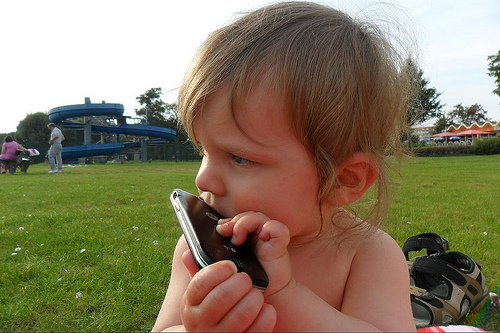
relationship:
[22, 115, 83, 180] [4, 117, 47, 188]
man and woman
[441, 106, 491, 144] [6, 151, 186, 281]
canopy at park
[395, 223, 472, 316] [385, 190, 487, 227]
item on ground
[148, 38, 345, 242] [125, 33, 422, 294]
head of kid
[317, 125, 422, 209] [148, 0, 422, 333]
ear of boy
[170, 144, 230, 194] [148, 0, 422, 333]
nose of boy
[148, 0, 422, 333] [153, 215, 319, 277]
boy with phone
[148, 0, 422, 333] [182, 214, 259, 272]
boy with plane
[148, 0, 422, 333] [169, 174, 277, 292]
boy mouthing phone